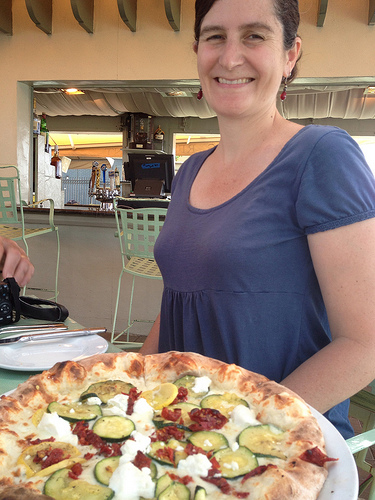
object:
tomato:
[77, 423, 100, 447]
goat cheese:
[112, 460, 156, 500]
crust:
[57, 352, 220, 373]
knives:
[0, 333, 57, 347]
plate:
[0, 331, 108, 374]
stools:
[110, 204, 153, 346]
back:
[134, 178, 163, 195]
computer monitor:
[133, 179, 164, 197]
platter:
[309, 402, 360, 500]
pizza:
[2, 348, 325, 500]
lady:
[149, 0, 372, 432]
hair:
[194, 0, 302, 85]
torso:
[171, 296, 374, 416]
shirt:
[161, 124, 375, 375]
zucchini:
[92, 415, 135, 442]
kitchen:
[28, 85, 375, 217]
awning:
[34, 79, 374, 119]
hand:
[0, 234, 34, 287]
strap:
[18, 295, 70, 321]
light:
[60, 85, 83, 97]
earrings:
[196, 86, 203, 101]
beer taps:
[100, 163, 108, 187]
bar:
[18, 204, 171, 225]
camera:
[0, 274, 22, 326]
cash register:
[123, 152, 171, 202]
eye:
[242, 33, 266, 43]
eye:
[204, 32, 227, 42]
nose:
[216, 48, 247, 74]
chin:
[208, 96, 257, 116]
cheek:
[247, 46, 280, 73]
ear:
[282, 38, 304, 78]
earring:
[281, 81, 287, 100]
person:
[3, 214, 41, 304]